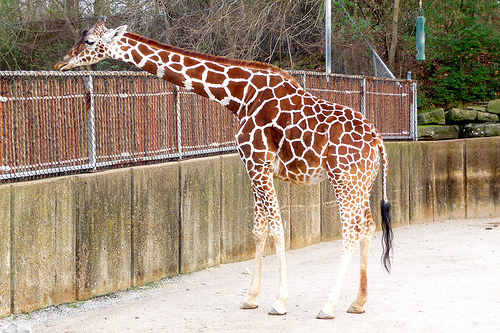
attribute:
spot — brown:
[58, 17, 427, 305]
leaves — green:
[406, 0, 498, 103]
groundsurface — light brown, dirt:
[416, 226, 483, 330]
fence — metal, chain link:
[0, 67, 415, 172]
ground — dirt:
[0, 217, 499, 332]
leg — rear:
[316, 159, 364, 318]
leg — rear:
[345, 187, 375, 312]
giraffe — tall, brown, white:
[43, 6, 396, 323]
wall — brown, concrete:
[15, 164, 162, 291]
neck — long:
[135, 10, 256, 126]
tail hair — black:
[380, 199, 394, 276]